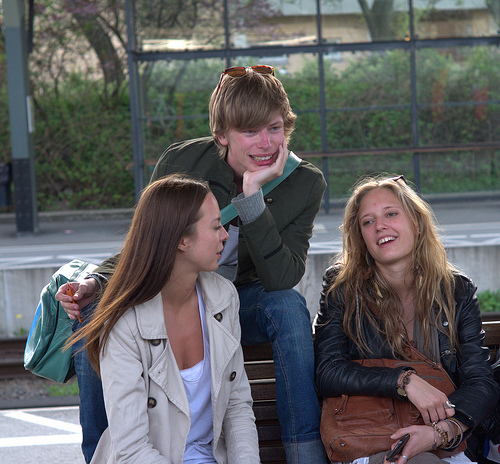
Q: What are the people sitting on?
A: Bench.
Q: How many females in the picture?
A: Two.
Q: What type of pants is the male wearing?
A: Jeans.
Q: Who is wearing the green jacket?
A: Male.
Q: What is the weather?
A: Cool.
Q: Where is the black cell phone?
A: In female's hand.